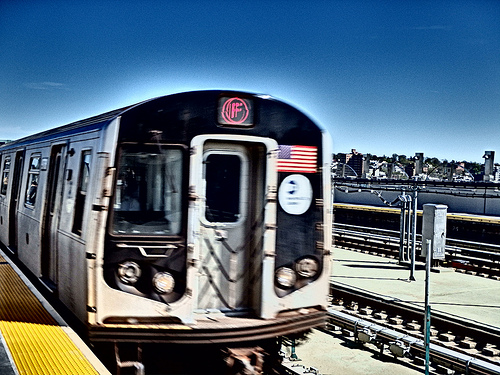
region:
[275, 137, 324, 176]
an American flag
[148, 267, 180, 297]
the head light of a train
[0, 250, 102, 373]
a yellow loading platform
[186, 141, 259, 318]
the door of a train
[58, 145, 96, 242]
a passenger window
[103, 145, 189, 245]
a front train window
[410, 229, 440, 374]
a gray sign post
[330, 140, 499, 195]
a small sky line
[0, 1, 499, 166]
a clear blue sky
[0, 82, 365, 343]
a gray train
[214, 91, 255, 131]
the letter f in a circle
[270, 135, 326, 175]
the American flag on a train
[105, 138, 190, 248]
a train's clear windshield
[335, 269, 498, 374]
metal railroad tracks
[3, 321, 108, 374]
yellow paint on a train platform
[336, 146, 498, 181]
a city skyline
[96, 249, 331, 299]
four lights on a train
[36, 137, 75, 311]
a subway train door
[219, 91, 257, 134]
the letter f on a subway car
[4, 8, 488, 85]
a deep blue sky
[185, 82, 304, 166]
the train has a letter on the front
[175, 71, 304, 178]
the letter is red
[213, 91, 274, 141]
the letter has a circle around it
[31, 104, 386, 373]
the train is black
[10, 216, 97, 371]
the platform is yellow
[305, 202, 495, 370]
tracks are next to the train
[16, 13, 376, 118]
the sky is blue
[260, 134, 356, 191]
a flag is on the train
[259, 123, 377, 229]
the flag is red white and blue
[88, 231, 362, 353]
the lights on the train are circular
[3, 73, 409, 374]
a train on train tracks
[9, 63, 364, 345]
the train is silver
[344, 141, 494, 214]
buildings in the distance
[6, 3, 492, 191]
the sky is blue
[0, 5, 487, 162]
the sky is clear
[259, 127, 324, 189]
the train has an american flag on it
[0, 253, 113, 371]
the walkway is yellow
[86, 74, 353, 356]
the train has a door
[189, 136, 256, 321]
the door has a window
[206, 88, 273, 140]
a pink letter f inside a circle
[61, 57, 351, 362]
A back view of a train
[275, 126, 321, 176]
Back of the train has the American flag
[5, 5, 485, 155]
The sky is clear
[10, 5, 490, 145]
The sky is blue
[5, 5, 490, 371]
Photo was taken in the daytime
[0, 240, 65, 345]
The train is casting a shadow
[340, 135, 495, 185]
Buildings are in the background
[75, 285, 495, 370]
Train is on train tracks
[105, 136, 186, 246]
Train has a window on the back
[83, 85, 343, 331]
The back of the train is black and white